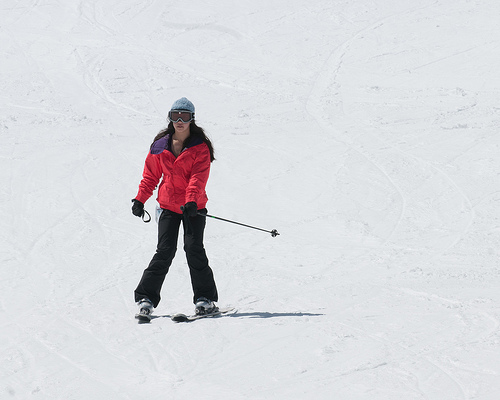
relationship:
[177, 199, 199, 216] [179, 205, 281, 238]
hand holding pole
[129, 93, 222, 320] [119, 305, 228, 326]
female on skis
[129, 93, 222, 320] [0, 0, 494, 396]
female going down slope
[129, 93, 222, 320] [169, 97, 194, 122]
female wears beanie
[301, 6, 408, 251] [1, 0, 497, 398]
mark on snow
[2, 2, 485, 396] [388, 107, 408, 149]
ground covered in snow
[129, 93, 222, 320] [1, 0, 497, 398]
female skiing on snow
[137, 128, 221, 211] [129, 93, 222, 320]
coat on female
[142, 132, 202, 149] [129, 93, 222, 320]
hood on female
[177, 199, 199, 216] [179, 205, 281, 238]
hand on pole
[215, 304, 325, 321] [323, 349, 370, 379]
shadow on snow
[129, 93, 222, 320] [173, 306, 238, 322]
female on skis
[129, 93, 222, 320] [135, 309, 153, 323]
female on skis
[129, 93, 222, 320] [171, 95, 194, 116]
female wears beanie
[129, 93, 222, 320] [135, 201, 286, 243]
female holds poles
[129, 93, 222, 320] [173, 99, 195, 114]
female wears beanie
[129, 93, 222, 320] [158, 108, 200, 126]
female wearing goggles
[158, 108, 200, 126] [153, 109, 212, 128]
goggles over eyes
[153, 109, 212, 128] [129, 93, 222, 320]
eyes of female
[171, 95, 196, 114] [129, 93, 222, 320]
beanie on female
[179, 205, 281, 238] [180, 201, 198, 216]
pole in hand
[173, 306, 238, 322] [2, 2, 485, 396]
skis is on ground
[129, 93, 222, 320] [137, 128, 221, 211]
female wears coat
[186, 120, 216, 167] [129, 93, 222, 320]
long hair of female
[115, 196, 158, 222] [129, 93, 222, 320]
glove on female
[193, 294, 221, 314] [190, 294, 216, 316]
ski shoe on foot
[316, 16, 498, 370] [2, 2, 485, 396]
snow covering ground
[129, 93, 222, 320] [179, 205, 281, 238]
female holding pole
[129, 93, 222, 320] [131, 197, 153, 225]
female holding ski pole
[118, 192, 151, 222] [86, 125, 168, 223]
ski pole on hand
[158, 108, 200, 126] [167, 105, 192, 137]
goggles on face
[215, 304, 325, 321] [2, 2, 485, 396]
shadow on ground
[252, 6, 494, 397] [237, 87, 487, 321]
track marks seen in snow